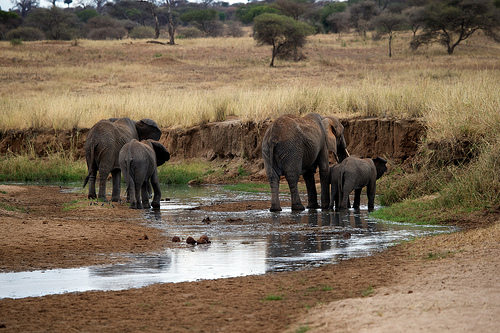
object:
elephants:
[79, 112, 163, 204]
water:
[1, 183, 475, 297]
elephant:
[250, 106, 349, 217]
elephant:
[321, 150, 391, 215]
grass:
[0, 32, 499, 224]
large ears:
[130, 111, 168, 145]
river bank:
[0, 185, 500, 332]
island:
[187, 185, 322, 218]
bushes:
[243, 6, 320, 68]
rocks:
[169, 219, 220, 249]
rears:
[253, 110, 317, 172]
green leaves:
[259, 17, 284, 35]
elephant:
[107, 133, 179, 211]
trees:
[356, 0, 412, 61]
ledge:
[0, 122, 500, 164]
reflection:
[179, 226, 358, 265]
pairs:
[76, 105, 176, 216]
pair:
[251, 108, 393, 218]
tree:
[153, 0, 197, 51]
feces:
[172, 229, 219, 250]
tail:
[76, 140, 101, 194]